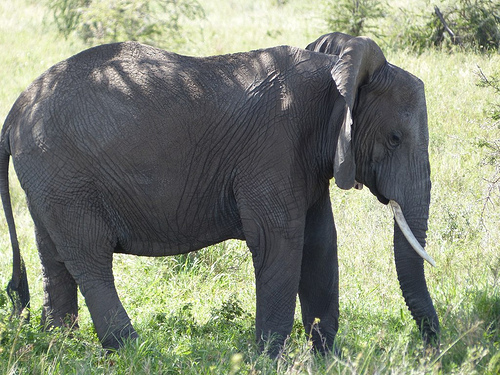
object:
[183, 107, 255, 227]
flesh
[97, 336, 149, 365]
feet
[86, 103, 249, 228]
skin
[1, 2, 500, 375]
field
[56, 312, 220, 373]
grass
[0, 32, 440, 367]
elephant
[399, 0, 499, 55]
tree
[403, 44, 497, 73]
grass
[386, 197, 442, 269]
tusk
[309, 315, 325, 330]
flower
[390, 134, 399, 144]
eye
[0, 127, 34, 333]
tail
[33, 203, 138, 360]
legs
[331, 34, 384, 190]
ear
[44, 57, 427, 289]
wrinkles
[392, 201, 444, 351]
trunk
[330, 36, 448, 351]
head